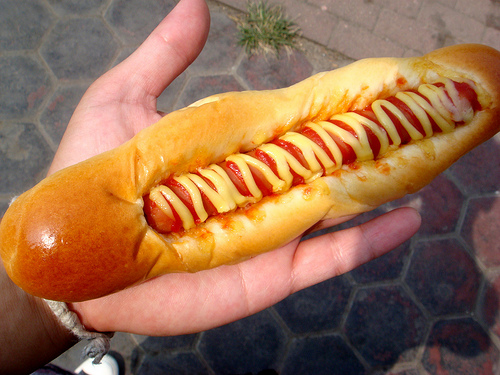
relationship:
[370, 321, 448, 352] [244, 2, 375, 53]
shadow on ground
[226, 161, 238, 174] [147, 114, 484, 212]
ketchup on hotdog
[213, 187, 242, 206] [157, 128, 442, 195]
mustard on hotdog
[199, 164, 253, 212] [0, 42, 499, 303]
cheese on .sandwich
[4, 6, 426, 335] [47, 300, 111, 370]
person wearing bracelet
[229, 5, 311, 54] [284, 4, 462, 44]
weed in sidewalk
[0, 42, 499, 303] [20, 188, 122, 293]
.sandwich baked bun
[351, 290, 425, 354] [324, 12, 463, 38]
bricks in sidewalk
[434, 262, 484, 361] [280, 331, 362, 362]
graffiti on bricks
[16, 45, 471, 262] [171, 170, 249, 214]
.sandwich with .cheese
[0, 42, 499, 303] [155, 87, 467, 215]
.sandwich with cheese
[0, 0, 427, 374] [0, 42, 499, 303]
person holds .sandwich